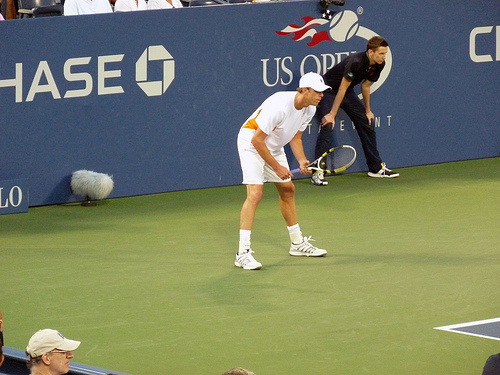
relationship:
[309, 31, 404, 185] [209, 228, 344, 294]
boy wearing shoe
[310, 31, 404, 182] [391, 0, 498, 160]
boy standing against wall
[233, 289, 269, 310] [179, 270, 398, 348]
part of floor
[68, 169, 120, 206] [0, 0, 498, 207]
bag against wall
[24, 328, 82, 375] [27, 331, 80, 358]
man in cap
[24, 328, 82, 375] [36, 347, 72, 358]
man in glasses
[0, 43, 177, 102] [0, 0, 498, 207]
sponsorship logo on wall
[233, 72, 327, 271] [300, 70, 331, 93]
man wearing cap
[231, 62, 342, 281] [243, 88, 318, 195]
man wearing outfit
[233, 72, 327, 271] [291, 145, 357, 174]
man holding racket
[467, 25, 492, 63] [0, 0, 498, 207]
letter c on wall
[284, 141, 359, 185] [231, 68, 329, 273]
racket held by player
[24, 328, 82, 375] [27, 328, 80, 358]
man wearing cap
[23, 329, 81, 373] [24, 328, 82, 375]
head of man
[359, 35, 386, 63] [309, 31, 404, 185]
head of boy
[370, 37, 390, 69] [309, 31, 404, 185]
face of boy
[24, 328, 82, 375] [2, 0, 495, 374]
man in tennis match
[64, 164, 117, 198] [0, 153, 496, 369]
mike sitting on court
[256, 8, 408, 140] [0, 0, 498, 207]
logo on wall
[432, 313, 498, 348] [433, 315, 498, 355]
stripe on tennis court